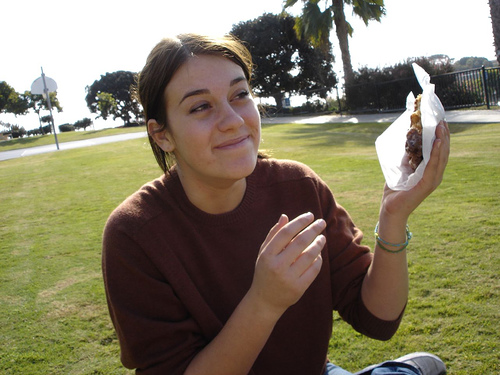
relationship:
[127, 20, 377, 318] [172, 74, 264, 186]
girl has a face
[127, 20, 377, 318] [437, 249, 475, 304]
girl sitting in grass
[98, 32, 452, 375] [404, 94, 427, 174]
girl holding hotdog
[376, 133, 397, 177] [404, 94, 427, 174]
wrapper with hotdog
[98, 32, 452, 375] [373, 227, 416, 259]
girl wearing bracelets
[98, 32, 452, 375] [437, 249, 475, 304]
girl sitting in grass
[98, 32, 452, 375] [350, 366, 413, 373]
girl wearing jeans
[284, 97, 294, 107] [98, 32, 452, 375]
sign behind girl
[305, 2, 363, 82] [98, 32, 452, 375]
palm tree behind girl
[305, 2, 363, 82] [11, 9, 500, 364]
palm tree in park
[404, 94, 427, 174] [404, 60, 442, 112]
hotdog wrapped in paper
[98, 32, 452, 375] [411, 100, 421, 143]
girl holding hotdog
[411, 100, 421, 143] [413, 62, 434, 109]
hotdog wrapped in wax paper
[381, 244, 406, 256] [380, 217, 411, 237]
bracelet on wrist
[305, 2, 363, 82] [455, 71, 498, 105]
palm tree beside fence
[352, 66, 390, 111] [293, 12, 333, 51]
tree with leaves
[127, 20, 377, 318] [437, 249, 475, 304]
girl sitting on grass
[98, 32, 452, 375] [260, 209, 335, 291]
girl has a hand